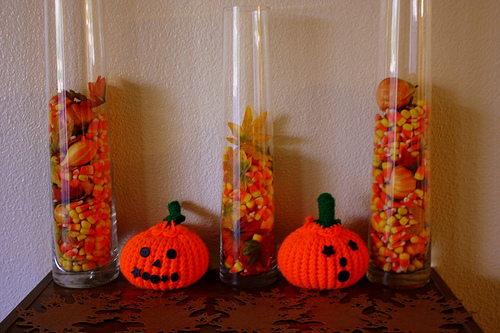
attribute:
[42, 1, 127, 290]
container — glass, tall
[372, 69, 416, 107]
candy piece — pictured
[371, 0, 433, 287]
container — tall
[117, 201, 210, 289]
pumpkin face — crocheted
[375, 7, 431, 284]
container — clear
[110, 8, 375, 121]
walls — white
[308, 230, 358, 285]
face — crocheted, pumpkin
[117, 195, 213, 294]
pumpkin — orange, fake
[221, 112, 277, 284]
candy — variety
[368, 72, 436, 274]
candy — variety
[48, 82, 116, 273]
candy — variety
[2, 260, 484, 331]
table — brown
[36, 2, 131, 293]
container — clear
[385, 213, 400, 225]
candy — yellow, orange, white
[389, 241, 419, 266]
candy — yellow, orange, white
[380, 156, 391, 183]
candy — yellow, orange, white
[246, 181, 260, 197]
candy — yellow, orange, white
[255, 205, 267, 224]
candy — yellow, orange, white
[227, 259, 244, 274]
candy — yellow, orange, white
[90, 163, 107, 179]
candy — yellow, orange, white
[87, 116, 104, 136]
candy — yellow, orange, white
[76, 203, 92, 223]
candy — yellow, orange, white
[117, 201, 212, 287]
pumpkin — orange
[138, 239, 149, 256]
eye — black, circle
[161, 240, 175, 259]
eye — black, circle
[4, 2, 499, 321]
wall — rough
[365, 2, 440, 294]
bottle — glass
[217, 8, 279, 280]
container — clear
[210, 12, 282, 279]
container — glass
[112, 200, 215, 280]
pumpkin — smiling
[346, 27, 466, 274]
container — glass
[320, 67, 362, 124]
wall —   rough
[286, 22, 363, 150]
wall — rough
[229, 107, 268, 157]
flower — yellow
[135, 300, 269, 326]
surface — brown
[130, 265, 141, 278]
star — black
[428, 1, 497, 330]
wall — rough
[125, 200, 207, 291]
pumpkin — crocheted